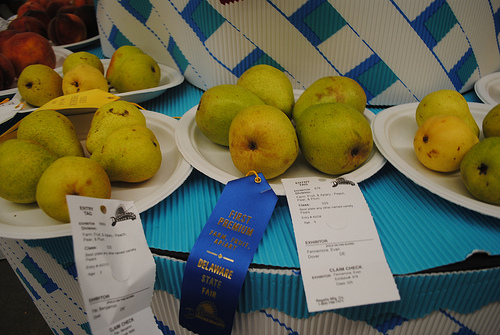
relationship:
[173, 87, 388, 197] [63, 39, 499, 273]
plate on top of table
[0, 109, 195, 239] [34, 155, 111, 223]
plate with pear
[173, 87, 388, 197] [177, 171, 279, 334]
plate with ribbon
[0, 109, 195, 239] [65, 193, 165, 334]
plate with tag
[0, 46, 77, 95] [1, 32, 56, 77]
plate with peach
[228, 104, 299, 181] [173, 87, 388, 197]
pear on top of plate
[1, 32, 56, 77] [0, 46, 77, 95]
peach on top of plate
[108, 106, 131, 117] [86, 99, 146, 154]
bruising on side of pear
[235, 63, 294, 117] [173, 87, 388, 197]
pear sitting on plate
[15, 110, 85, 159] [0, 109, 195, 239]
pear on top of plate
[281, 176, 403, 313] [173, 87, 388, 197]
tag attached to plate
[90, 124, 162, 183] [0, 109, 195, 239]
pear on top of plate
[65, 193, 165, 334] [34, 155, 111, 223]
tag near pear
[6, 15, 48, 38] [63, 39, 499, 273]
peach on top of table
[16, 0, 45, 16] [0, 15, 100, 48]
peach on top of plate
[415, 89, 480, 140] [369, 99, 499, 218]
pear sitting on plate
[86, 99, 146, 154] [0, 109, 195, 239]
pear on top of plate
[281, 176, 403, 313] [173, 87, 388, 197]
tag on side of plate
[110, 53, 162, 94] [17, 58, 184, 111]
pear on top of plate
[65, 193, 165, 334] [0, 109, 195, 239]
tag on side of plate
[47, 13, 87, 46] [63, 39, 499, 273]
peach on top of table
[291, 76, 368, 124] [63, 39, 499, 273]
pear on top of table